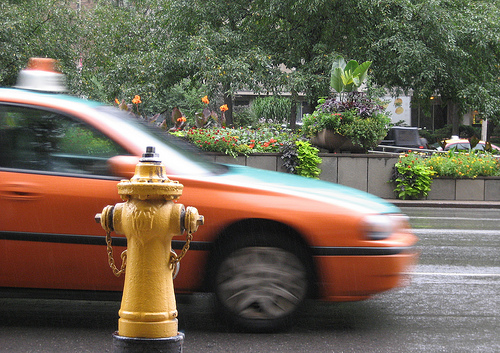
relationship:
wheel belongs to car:
[208, 222, 317, 336] [2, 55, 417, 333]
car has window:
[2, 55, 417, 333] [3, 101, 133, 180]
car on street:
[2, 55, 417, 333] [0, 205, 495, 351]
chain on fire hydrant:
[97, 235, 127, 279] [93, 146, 208, 352]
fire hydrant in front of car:
[93, 141, 211, 346] [2, 55, 417, 333]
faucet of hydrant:
[92, 202, 116, 234] [95, 145, 206, 351]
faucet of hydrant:
[179, 202, 204, 234] [95, 145, 206, 351]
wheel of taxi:
[209, 222, 317, 332] [0, 53, 421, 335]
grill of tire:
[216, 246, 303, 318] [243, 228, 305, 250]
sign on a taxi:
[24, 56, 68, 98] [0, 85, 422, 330]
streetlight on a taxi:
[346, 205, 421, 242] [228, 164, 406, 289]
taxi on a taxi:
[228, 164, 406, 289] [68, 145, 423, 291]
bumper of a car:
[0, 230, 403, 257] [2, 55, 417, 333]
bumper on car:
[333, 245, 408, 291] [2, 55, 417, 333]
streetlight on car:
[359, 214, 393, 241] [2, 55, 417, 333]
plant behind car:
[392, 150, 433, 200] [2, 55, 417, 333]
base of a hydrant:
[110, 328, 194, 351] [110, 152, 191, 346]